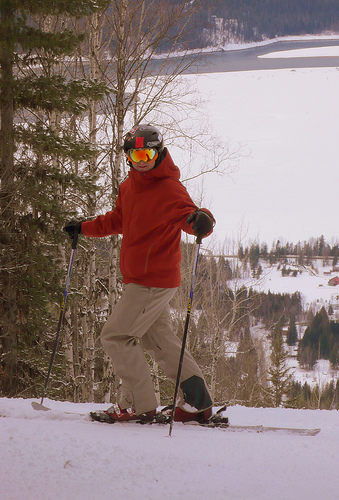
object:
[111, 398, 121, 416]
strap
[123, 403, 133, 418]
strap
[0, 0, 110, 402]
evergreen tree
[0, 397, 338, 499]
hill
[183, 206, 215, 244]
glove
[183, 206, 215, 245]
hand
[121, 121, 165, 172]
helmet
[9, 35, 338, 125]
river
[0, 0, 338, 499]
landscape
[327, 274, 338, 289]
house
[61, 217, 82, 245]
glove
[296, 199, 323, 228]
part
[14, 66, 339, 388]
snow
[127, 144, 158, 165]
goggles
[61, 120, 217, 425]
man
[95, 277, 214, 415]
pants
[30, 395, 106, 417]
skis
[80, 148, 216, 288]
jacket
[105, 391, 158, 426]
ski boots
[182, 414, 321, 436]
skis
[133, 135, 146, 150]
sticker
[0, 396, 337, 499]
snow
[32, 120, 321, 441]
skate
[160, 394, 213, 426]
ski boots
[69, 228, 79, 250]
handles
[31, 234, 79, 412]
ski pole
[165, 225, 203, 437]
ski pole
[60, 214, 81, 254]
hand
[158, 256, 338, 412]
valley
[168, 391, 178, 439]
edge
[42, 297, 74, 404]
part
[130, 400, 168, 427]
part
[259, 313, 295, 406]
trees